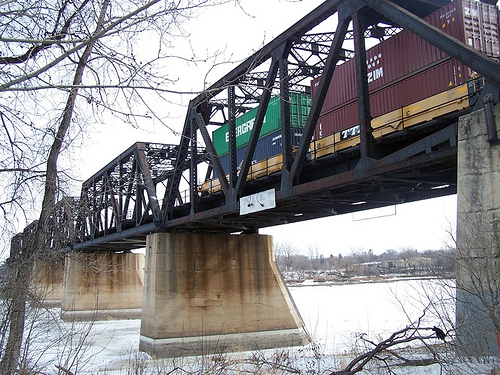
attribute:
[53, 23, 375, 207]
bridge — steel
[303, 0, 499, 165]
crate — maroon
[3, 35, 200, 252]
trees — bare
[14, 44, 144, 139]
branches — thin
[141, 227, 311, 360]
pillar — gray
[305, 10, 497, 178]
crate — maroon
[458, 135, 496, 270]
pillars — large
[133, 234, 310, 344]
pillar — brown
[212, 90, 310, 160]
crate — green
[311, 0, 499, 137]
containers — metal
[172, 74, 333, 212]
bridge — black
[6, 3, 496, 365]
bridge — metal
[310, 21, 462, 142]
car — dark brown, metal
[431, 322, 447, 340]
object — black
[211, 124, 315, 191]
crate — dark blue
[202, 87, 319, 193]
train — green and blue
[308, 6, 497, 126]
train car — red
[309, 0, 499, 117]
crate — maroon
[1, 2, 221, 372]
tree — bare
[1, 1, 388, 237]
sky — bright